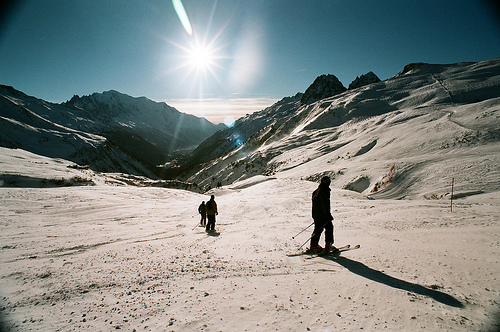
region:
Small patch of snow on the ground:
[231, 270, 253, 290]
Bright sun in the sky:
[185, 40, 220, 70]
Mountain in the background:
[111, 102, 136, 126]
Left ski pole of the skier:
[288, 220, 314, 237]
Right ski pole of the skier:
[298, 230, 314, 250]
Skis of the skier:
[338, 242, 367, 259]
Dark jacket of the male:
[312, 196, 328, 216]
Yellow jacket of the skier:
[207, 205, 217, 215]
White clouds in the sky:
[210, 105, 236, 117]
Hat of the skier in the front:
[320, 175, 331, 186]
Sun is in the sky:
[155, 12, 242, 88]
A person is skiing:
[286, 166, 363, 268]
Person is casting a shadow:
[325, 244, 476, 322]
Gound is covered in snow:
[1, 193, 498, 325]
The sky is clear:
[16, 5, 496, 97]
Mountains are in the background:
[3, 73, 238, 173]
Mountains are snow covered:
[4, 71, 224, 161]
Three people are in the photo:
[187, 165, 349, 270]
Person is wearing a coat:
[296, 180, 339, 225]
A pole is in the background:
[443, 171, 460, 216]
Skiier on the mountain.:
[285, 171, 357, 261]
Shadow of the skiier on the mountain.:
[310, 241, 465, 308]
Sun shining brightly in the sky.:
[145, 2, 275, 93]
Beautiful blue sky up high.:
[0, 2, 490, 103]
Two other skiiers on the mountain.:
[195, 190, 220, 235]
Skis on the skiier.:
[284, 242, 363, 262]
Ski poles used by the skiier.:
[291, 215, 318, 256]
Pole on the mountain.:
[440, 176, 466, 217]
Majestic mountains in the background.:
[2, 62, 491, 198]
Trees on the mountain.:
[73, 102, 492, 182]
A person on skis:
[289, 154, 391, 305]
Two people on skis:
[163, 169, 238, 253]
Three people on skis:
[144, 165, 387, 264]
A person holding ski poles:
[285, 144, 366, 289]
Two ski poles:
[274, 207, 328, 265]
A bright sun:
[104, 22, 273, 104]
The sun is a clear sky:
[103, 9, 313, 123]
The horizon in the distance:
[131, 85, 324, 125]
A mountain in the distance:
[35, 81, 225, 163]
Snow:
[177, 235, 328, 311]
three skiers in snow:
[189, 176, 363, 263]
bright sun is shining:
[156, 24, 232, 93]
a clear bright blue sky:
[2, 0, 490, 100]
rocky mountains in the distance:
[0, 50, 227, 162]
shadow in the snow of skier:
[319, 245, 465, 312]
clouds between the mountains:
[157, 94, 282, 128]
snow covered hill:
[306, 54, 497, 196]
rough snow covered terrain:
[11, 249, 258, 330]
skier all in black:
[303, 174, 340, 256]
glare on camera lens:
[216, 109, 247, 156]